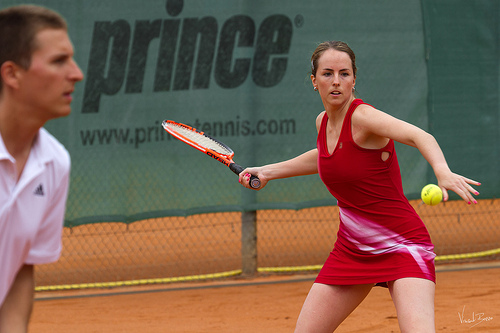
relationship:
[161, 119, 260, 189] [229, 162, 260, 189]
racket has grip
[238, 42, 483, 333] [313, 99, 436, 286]
player wearing dress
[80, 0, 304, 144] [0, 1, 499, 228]
ad on fence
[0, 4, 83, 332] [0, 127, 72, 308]
man in shirt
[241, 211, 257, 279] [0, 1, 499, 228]
pole on fence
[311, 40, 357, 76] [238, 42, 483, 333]
hair of player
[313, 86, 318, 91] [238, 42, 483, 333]
earrings on player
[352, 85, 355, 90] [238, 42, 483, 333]
earrings on player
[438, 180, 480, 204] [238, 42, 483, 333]
nails on player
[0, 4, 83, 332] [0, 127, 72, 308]
man wearing shirt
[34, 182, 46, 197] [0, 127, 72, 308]
logo on shirt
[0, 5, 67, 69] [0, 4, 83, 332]
hair on man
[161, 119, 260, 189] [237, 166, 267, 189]
racket in hand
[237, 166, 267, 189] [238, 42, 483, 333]
hand of player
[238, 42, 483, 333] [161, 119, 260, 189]
player swinging racket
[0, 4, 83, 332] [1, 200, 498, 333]
man on court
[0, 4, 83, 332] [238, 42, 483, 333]
man and player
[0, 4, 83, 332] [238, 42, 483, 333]
man near player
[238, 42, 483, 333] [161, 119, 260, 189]
player holding racket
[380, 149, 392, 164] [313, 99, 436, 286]
hole in dress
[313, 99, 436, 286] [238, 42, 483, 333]
dress on player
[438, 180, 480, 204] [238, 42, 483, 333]
nails of player